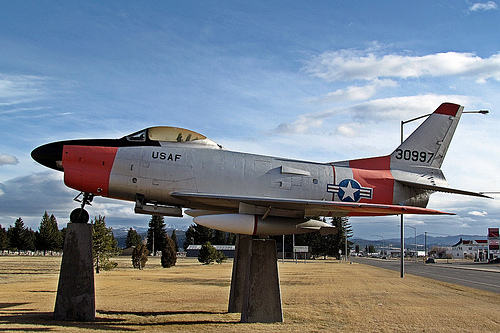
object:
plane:
[25, 101, 495, 239]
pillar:
[46, 221, 103, 325]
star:
[338, 180, 361, 202]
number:
[394, 148, 438, 166]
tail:
[390, 101, 465, 177]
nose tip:
[25, 142, 54, 169]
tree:
[36, 210, 54, 258]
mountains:
[353, 222, 489, 247]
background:
[0, 209, 499, 291]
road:
[347, 255, 500, 294]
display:
[27, 98, 497, 321]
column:
[238, 242, 284, 325]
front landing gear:
[66, 191, 96, 224]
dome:
[127, 127, 212, 145]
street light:
[478, 106, 493, 117]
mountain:
[115, 226, 145, 248]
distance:
[0, 222, 500, 263]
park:
[0, 255, 497, 333]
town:
[445, 226, 500, 267]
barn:
[185, 242, 238, 257]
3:
[394, 148, 405, 162]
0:
[402, 148, 412, 161]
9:
[410, 149, 419, 163]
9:
[419, 150, 426, 163]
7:
[427, 150, 435, 163]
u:
[151, 150, 159, 159]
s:
[160, 151, 167, 160]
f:
[174, 153, 183, 163]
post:
[225, 235, 253, 315]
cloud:
[296, 38, 497, 99]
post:
[465, 106, 491, 117]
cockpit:
[119, 122, 219, 149]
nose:
[191, 211, 254, 236]